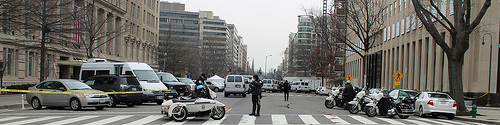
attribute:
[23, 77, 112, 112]
vehicle — parked, gray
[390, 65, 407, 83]
sign — yellow, black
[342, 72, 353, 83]
sign — yellow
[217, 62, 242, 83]
traffic light — red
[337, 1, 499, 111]
building — tan, brick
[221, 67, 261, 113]
van — white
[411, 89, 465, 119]
car — white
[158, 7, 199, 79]
building — tall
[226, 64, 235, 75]
signal — red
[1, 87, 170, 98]
tape — yellow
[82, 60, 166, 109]
van — white, large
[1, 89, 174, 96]
tape — yellow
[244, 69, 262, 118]
officer — police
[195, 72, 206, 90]
officer — police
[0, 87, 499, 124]
street — city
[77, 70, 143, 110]
vehicle — grey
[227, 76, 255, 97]
van — white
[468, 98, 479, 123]
fire hydrant — green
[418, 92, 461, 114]
car — grey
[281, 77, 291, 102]
person — wearing black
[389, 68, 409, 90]
sign — yellow